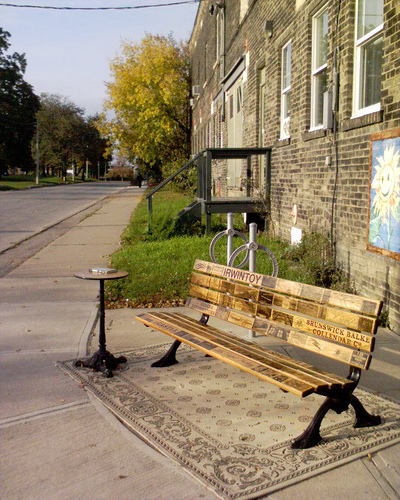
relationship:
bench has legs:
[131, 259, 385, 451] [287, 393, 381, 450]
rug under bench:
[53, 337, 400, 499] [131, 259, 385, 451]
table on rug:
[71, 269, 132, 379] [53, 337, 400, 499]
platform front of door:
[196, 193, 268, 237] [256, 80, 266, 189]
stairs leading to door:
[158, 198, 203, 236] [256, 80, 266, 189]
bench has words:
[131, 259, 385, 451] [304, 319, 371, 349]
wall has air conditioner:
[184, 1, 399, 342] [191, 82, 201, 96]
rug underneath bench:
[53, 337, 400, 499] [131, 259, 385, 451]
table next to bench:
[71, 269, 132, 379] [131, 259, 385, 451]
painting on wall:
[363, 125, 399, 261] [184, 1, 399, 342]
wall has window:
[184, 1, 399, 342] [274, 31, 301, 141]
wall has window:
[184, 1, 399, 342] [300, 0, 336, 132]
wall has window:
[184, 1, 399, 342] [347, 0, 392, 119]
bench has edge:
[131, 259, 385, 451] [298, 378, 359, 399]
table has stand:
[71, 269, 132, 379] [97, 281, 108, 352]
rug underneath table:
[53, 337, 400, 499] [71, 269, 132, 379]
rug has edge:
[53, 337, 400, 499] [192, 478, 225, 499]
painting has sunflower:
[363, 125, 399, 261] [371, 146, 400, 246]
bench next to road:
[131, 259, 385, 451] [0, 177, 140, 280]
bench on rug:
[131, 259, 385, 451] [53, 337, 400, 499]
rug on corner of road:
[53, 337, 400, 499] [0, 177, 140, 280]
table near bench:
[71, 269, 132, 379] [131, 259, 385, 451]